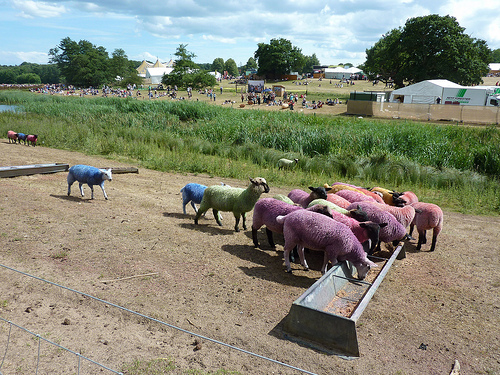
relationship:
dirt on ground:
[119, 211, 149, 226] [24, 234, 216, 310]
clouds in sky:
[151, 3, 221, 31] [19, 30, 63, 43]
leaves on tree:
[75, 60, 115, 81] [351, 2, 498, 84]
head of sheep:
[94, 161, 115, 187] [52, 169, 109, 200]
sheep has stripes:
[52, 169, 109, 200] [201, 195, 210, 203]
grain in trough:
[329, 297, 355, 312] [298, 278, 409, 311]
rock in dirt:
[75, 265, 97, 275] [119, 211, 149, 226]